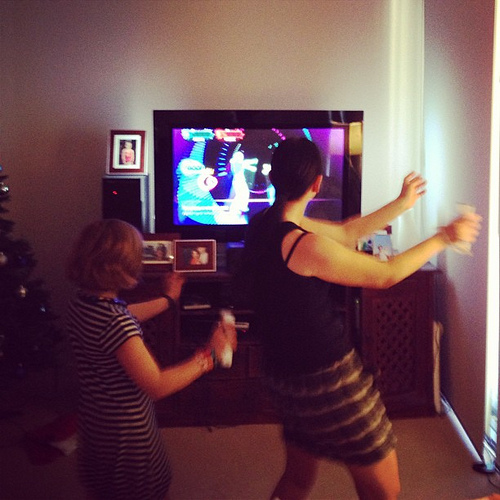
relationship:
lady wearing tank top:
[245, 138, 484, 499] [246, 210, 356, 370]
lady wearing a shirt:
[245, 138, 484, 499] [240, 211, 358, 379]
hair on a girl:
[66, 218, 145, 291] [60, 211, 237, 498]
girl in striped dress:
[60, 211, 237, 498] [57, 288, 172, 496]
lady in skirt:
[249, 140, 479, 495] [267, 349, 403, 465]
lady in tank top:
[249, 140, 479, 495] [246, 210, 356, 370]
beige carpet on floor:
[1, 412, 489, 498] [7, 360, 498, 497]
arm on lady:
[278, 228, 448, 290] [245, 138, 484, 499]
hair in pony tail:
[233, 136, 322, 333] [254, 192, 289, 282]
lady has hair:
[245, 138, 484, 499] [233, 136, 322, 333]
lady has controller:
[245, 138, 484, 499] [453, 203, 482, 260]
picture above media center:
[97, 98, 173, 230] [72, 191, 454, 427]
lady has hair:
[245, 138, 484, 499] [217, 126, 328, 354]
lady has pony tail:
[245, 138, 484, 499] [257, 180, 294, 241]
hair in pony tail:
[217, 126, 328, 354] [257, 180, 294, 241]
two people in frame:
[180, 226, 212, 278] [170, 236, 223, 266]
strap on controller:
[434, 226, 454, 247] [453, 203, 480, 255]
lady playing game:
[245, 138, 484, 499] [173, 128, 345, 228]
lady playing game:
[245, 138, 484, 499] [170, 125, 354, 243]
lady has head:
[245, 138, 484, 499] [265, 131, 322, 211]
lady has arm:
[245, 138, 484, 499] [303, 212, 418, 242]